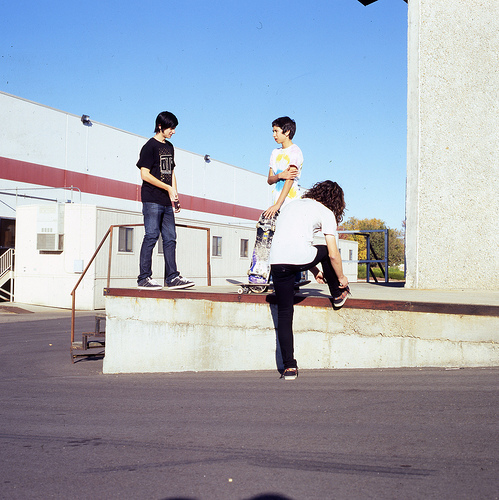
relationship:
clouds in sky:
[347, 149, 408, 219] [345, 111, 403, 216]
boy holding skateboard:
[263, 115, 303, 190] [238, 209, 281, 293]